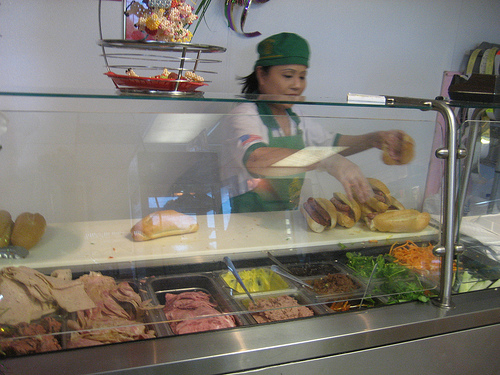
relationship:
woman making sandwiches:
[210, 24, 420, 210] [296, 176, 432, 237]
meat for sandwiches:
[166, 281, 234, 334] [296, 176, 432, 237]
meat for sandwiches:
[161, 291, 236, 336] [296, 176, 432, 237]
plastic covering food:
[3, 108, 445, 332] [5, 172, 493, 359]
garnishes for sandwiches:
[3, 233, 498, 355] [296, 176, 432, 237]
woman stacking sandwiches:
[210, 24, 420, 210] [296, 176, 432, 237]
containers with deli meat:
[4, 251, 241, 368] [1, 258, 233, 335]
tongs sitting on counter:
[2, 242, 32, 263] [1, 211, 300, 274]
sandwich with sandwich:
[302, 195, 328, 227] [299, 196, 337, 233]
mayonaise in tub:
[223, 262, 290, 294] [213, 261, 306, 302]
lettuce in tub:
[348, 251, 425, 308] [329, 241, 443, 311]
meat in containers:
[166, 281, 234, 334] [143, 273, 251, 338]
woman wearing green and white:
[210, 24, 420, 210] [214, 23, 344, 214]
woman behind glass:
[210, 24, 420, 210] [3, 108, 445, 332]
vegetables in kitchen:
[364, 274, 439, 309] [2, 5, 500, 368]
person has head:
[210, 24, 420, 210] [230, 26, 321, 122]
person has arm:
[210, 24, 420, 210] [235, 114, 377, 208]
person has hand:
[210, 24, 420, 210] [321, 145, 378, 208]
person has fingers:
[210, 24, 420, 210] [341, 171, 378, 203]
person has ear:
[210, 24, 420, 210] [251, 62, 270, 85]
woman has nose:
[210, 24, 420, 210] [291, 74, 303, 91]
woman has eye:
[210, 24, 420, 210] [282, 71, 297, 83]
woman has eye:
[210, 24, 420, 210] [297, 71, 308, 82]